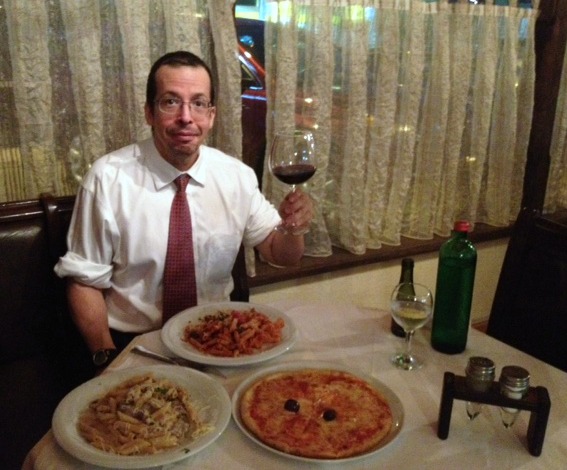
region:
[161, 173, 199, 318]
Red tie worn by a man.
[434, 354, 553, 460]
Salt and pepper shakers in a wooden holder.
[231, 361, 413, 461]
A pizza on a white plate.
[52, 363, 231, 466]
Pasta with white sauce on a white plate.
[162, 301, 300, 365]
Pasta with red sauce on a white plate.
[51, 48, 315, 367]
Man wearing a white shirt.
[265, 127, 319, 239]
Clear wine glass with red wine in it.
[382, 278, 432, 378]
Clear wine glass with white wine in it.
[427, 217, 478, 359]
Large green bottle with a red top.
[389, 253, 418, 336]
Small green bottle on table.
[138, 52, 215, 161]
the head of a man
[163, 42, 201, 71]
the hair of a man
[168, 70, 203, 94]
the forehead of a man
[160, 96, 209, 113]
the eyes of a man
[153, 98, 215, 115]
the glasses of a man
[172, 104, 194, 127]
the nose of a man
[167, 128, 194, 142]
the mouth of a man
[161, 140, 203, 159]
the chin of a man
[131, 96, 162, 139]
the right ear of a man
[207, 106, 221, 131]
the left ear of a man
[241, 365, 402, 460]
Pizza on a plate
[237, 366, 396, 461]
Pizza is on a plate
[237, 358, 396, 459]
Pizza on a white plate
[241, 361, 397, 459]
Pizza is on a white plate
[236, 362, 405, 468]
Whole pizza on a plate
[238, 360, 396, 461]
Whole pizza is on a plate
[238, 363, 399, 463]
Whole pizza on a white plate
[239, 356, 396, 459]
Whole pizza is on a white plate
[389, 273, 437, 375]
Wine glass on a table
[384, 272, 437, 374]
Wine glass is on a table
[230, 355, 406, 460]
Small cheese pizza on a plate.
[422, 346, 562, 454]
Salt and pepper shaker on the table.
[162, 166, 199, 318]
Long red tie around man's neck.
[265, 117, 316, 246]
Glass of red wine in man's hand.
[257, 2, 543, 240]
White curtains covering the window.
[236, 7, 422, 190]
Front of red car parked on the side of the road.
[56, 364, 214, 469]
Bowl of pasta on the table.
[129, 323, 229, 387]
Silver fork lying on the table.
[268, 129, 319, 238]
A wine glass with dark wine in it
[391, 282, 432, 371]
A wine glass with clear wine in it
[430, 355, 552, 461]
A salt and pepper shaker holder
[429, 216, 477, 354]
A large plastic bottle of seltzer water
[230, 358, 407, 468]
A white plate with a cheese pizza on top of it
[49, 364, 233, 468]
A white plate with pasta on it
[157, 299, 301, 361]
A large white plate with pasta on it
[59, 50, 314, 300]
A man holding a wine glass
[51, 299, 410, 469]
Three white plates with food on them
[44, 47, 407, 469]
A man sitting down to eat dinner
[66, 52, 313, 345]
a person is sitting down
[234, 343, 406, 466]
a plate made for dining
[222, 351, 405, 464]
a plate made for dining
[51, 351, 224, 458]
a plate made for dining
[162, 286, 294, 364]
a plate made for dining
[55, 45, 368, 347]
man holding a wine glass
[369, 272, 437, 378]
wine glass on the table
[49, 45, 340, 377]
A man with his sleeves rolled up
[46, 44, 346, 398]
A man holding a wine glass up in the air.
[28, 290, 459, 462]
Food on top of a table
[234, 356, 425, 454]
A round pizza on a plate.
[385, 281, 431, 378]
A wine glass resting on top of the table